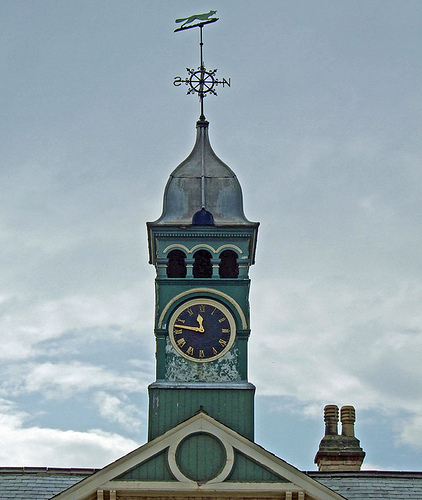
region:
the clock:
[147, 275, 210, 308]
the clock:
[127, 199, 279, 473]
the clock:
[156, 297, 305, 459]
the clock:
[118, 295, 243, 475]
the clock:
[172, 316, 243, 495]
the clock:
[199, 299, 276, 449]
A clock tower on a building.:
[118, 99, 280, 430]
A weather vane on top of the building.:
[143, 1, 260, 126]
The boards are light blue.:
[183, 446, 212, 463]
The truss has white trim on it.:
[37, 400, 343, 495]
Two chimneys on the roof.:
[304, 389, 370, 464]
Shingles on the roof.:
[1, 472, 41, 491]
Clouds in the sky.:
[10, 307, 124, 433]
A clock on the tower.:
[161, 283, 236, 366]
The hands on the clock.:
[170, 306, 215, 332]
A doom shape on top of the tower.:
[158, 133, 250, 219]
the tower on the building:
[128, 108, 278, 432]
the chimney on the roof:
[297, 395, 369, 471]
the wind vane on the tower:
[167, 8, 241, 102]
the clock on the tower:
[172, 300, 246, 360]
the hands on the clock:
[172, 314, 211, 335]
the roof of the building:
[5, 465, 421, 498]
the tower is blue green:
[6, 174, 418, 497]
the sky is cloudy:
[302, 107, 405, 334]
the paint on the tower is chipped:
[168, 343, 240, 385]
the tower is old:
[120, 39, 292, 447]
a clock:
[124, 185, 347, 493]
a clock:
[154, 284, 296, 384]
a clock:
[147, 268, 276, 497]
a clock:
[125, 245, 240, 405]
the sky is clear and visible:
[327, 120, 354, 215]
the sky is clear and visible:
[285, 293, 289, 296]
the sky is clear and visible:
[271, 148, 323, 267]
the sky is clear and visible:
[280, 243, 373, 434]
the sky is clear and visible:
[300, 262, 353, 448]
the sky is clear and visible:
[339, 325, 353, 430]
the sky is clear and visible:
[298, 302, 337, 436]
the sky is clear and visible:
[307, 142, 362, 387]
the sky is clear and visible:
[351, 221, 410, 448]